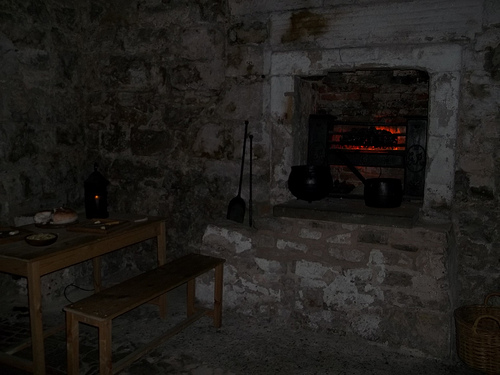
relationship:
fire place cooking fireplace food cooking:
[312, 114, 418, 154] [323, 107, 405, 166]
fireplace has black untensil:
[268, 44, 462, 229] [217, 103, 264, 234]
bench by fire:
[59, 252, 227, 375] [300, 112, 410, 165]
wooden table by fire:
[2, 199, 168, 374] [280, 79, 433, 204]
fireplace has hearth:
[197, 40, 469, 363] [198, 200, 457, 353]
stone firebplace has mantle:
[252, 31, 472, 362] [260, 40, 467, 215]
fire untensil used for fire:
[217, 103, 264, 234] [292, 79, 424, 203]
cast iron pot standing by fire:
[277, 154, 338, 208] [301, 105, 418, 195]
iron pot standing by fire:
[277, 154, 338, 208] [300, 119, 416, 199]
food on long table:
[27, 233, 56, 240] [0, 211, 166, 374]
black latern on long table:
[76, 160, 119, 224] [0, 211, 166, 374]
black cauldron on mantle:
[277, 154, 338, 208] [185, 140, 454, 355]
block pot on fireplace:
[277, 154, 338, 208] [197, 40, 469, 363]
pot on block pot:
[334, 154, 406, 213] [277, 154, 338, 208]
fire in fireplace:
[316, 113, 420, 165] [197, 40, 469, 363]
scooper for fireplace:
[219, 116, 251, 225] [197, 40, 469, 363]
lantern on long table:
[84, 163, 110, 219] [0, 211, 166, 374]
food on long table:
[21, 227, 60, 249] [0, 211, 166, 374]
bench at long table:
[59, 246, 229, 373] [0, 211, 166, 374]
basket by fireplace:
[450, 301, 495, 371] [197, 40, 469, 363]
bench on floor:
[59, 252, 227, 375] [4, 286, 457, 373]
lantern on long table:
[79, 156, 119, 222] [0, 211, 166, 374]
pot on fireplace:
[347, 165, 403, 207] [197, 40, 469, 363]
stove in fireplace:
[300, 106, 420, 209] [197, 40, 469, 363]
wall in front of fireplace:
[200, 207, 480, 366] [197, 40, 469, 363]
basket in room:
[450, 301, 495, 371] [4, 1, 493, 370]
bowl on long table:
[17, 227, 62, 249] [0, 211, 166, 374]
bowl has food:
[17, 227, 62, 249] [31, 229, 48, 239]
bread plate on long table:
[34, 201, 79, 228] [0, 211, 166, 374]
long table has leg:
[0, 211, 166, 374] [25, 277, 44, 373]